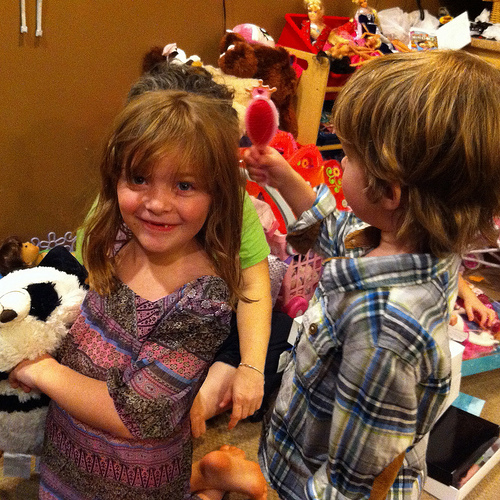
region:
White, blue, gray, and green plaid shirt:
[259, 185, 464, 498]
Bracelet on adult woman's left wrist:
[234, 357, 264, 379]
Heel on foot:
[199, 451, 232, 483]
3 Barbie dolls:
[297, 0, 398, 57]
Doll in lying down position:
[2, 236, 76, 273]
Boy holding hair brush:
[244, 53, 498, 497]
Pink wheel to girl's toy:
[286, 295, 310, 318]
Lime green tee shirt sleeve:
[240, 190, 271, 270]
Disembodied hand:
[457, 272, 499, 329]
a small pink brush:
[245, 97, 278, 155]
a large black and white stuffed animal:
[0, 247, 91, 467]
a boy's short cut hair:
[331, 44, 498, 254]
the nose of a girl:
[146, 180, 173, 214]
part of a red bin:
[276, 12, 382, 77]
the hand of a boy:
[245, 138, 290, 187]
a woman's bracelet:
[239, 359, 269, 378]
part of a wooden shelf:
[289, 45, 345, 162]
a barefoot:
[204, 450, 273, 498]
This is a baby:
[55, 94, 228, 497]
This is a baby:
[45, 91, 268, 495]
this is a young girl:
[14, 82, 271, 494]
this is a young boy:
[264, 22, 494, 492]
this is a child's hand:
[232, 240, 264, 430]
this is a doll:
[294, 0, 366, 59]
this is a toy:
[1, 270, 50, 473]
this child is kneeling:
[37, 71, 261, 496]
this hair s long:
[196, 92, 258, 286]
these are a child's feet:
[191, 445, 278, 497]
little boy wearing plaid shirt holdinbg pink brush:
[237, 46, 499, 498]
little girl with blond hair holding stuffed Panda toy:
[5, 98, 255, 492]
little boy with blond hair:
[324, 41, 499, 259]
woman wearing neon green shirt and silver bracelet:
[89, 55, 298, 431]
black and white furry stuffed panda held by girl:
[3, 240, 102, 470]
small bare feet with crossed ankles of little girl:
[191, 441, 265, 496]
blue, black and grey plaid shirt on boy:
[236, 175, 469, 498]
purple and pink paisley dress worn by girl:
[36, 258, 241, 494]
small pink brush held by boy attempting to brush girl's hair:
[241, 91, 286, 178]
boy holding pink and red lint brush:
[233, 80, 293, 182]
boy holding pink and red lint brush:
[234, 83, 301, 173]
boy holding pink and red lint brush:
[238, 80, 294, 164]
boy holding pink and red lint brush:
[229, 80, 291, 165]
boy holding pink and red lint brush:
[231, 78, 286, 156]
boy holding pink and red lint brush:
[224, 78, 302, 163]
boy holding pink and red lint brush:
[233, 82, 295, 162]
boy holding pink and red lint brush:
[229, 80, 294, 171]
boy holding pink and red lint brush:
[234, 82, 294, 167]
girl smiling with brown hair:
[61, 85, 257, 284]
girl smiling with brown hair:
[75, 88, 258, 300]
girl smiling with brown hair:
[66, 85, 266, 307]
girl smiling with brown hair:
[64, 36, 263, 307]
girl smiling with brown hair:
[69, 79, 269, 314]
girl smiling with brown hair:
[66, 79, 263, 316]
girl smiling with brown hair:
[59, 68, 266, 313]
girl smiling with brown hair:
[54, 80, 265, 315]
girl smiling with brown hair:
[54, 72, 271, 322]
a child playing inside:
[67, 71, 263, 499]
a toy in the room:
[221, 95, 296, 178]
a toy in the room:
[6, 225, 62, 320]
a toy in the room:
[301, 133, 334, 190]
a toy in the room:
[221, 28, 293, 95]